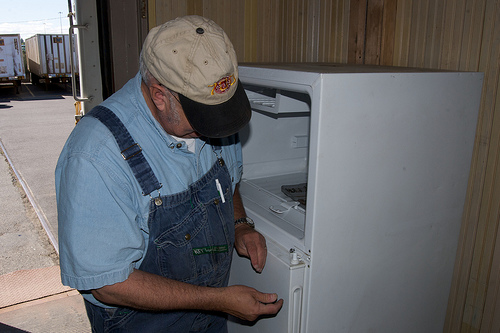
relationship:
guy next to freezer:
[51, 16, 280, 333] [210, 61, 485, 333]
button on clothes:
[154, 198, 163, 206] [57, 70, 242, 330]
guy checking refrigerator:
[48, 6, 289, 331] [239, 58, 461, 332]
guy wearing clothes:
[51, 16, 280, 333] [57, 70, 244, 333]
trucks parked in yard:
[0, 35, 70, 95] [2, 91, 51, 324]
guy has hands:
[51, 16, 280, 333] [222, 279, 286, 327]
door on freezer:
[226, 70, 314, 327] [210, 61, 485, 333]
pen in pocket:
[214, 177, 226, 204] [212, 185, 238, 255]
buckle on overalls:
[143, 182, 164, 204] [83, 103, 235, 331]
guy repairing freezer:
[51, 16, 280, 333] [210, 61, 485, 333]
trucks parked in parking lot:
[0, 28, 75, 95] [0, 25, 66, 287]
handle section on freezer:
[285, 286, 303, 326] [210, 61, 485, 333]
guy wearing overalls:
[51, 16, 280, 333] [66, 98, 239, 331]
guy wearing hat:
[51, 16, 280, 333] [142, 12, 254, 140]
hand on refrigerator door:
[208, 283, 284, 326] [223, 228, 307, 327]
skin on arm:
[91, 267, 219, 313] [61, 157, 226, 313]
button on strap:
[153, 199, 162, 210] [82, 106, 166, 209]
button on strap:
[215, 157, 222, 168] [82, 106, 166, 209]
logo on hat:
[209, 75, 236, 96] [142, 12, 254, 140]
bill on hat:
[179, 78, 253, 141] [142, 12, 254, 140]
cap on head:
[140, 17, 252, 138] [128, 8, 259, 146]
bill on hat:
[193, 94, 254, 136] [134, 10, 254, 146]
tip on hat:
[195, 25, 206, 35] [134, 10, 254, 146]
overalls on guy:
[106, 153, 263, 280] [51, 16, 280, 333]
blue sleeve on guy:
[53, 71, 239, 291] [51, 16, 280, 333]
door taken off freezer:
[226, 70, 314, 327] [217, 73, 487, 238]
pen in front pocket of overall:
[214, 177, 226, 204] [81, 104, 234, 331]